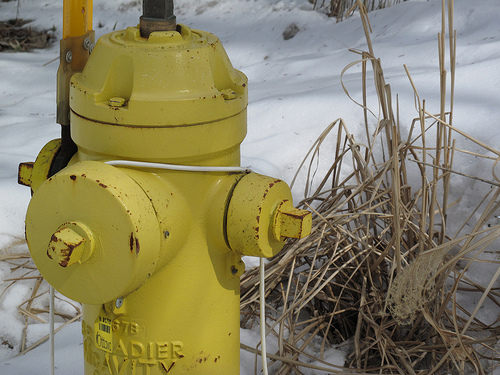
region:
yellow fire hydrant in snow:
[26, 6, 326, 359]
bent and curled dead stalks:
[315, 20, 475, 355]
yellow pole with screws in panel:
[50, 0, 95, 130]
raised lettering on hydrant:
[60, 317, 197, 369]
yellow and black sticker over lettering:
[60, 307, 145, 357]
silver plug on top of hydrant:
[125, 0, 180, 40]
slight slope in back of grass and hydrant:
[21, 5, 486, 140]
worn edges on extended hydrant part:
[11, 177, 163, 302]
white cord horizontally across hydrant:
[70, 141, 265, 187]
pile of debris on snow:
[0, 8, 56, 66]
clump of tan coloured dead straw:
[235, 3, 498, 373]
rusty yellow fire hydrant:
[12, 14, 318, 373]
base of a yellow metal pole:
[51, 0, 105, 138]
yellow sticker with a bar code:
[82, 317, 127, 357]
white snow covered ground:
[2, 0, 499, 373]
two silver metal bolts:
[51, 34, 99, 73]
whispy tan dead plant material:
[382, 236, 452, 325]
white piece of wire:
[95, 150, 275, 185]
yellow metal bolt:
[102, 86, 132, 113]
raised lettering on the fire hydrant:
[76, 316, 188, 373]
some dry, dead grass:
[242, 50, 482, 370]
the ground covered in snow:
[1, 4, 482, 367]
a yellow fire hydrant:
[1, 20, 267, 370]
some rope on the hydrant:
[16, 146, 301, 373]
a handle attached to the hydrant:
[24, 1, 99, 128]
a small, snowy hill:
[258, 0, 497, 160]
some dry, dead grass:
[313, 1, 390, 31]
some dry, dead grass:
[0, 7, 50, 51]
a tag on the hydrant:
[83, 306, 132, 363]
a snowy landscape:
[3, 5, 498, 341]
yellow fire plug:
[72, 18, 272, 373]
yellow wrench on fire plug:
[36, 1, 96, 145]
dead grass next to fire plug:
[270, 37, 455, 334]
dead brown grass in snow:
[280, 47, 490, 365]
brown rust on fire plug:
[36, 68, 245, 372]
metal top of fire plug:
[128, 2, 186, 34]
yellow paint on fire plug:
[47, 147, 187, 355]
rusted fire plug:
[16, 147, 161, 310]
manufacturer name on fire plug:
[88, 295, 210, 374]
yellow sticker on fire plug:
[85, 310, 125, 362]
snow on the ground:
[272, 71, 339, 129]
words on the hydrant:
[90, 305, 170, 371]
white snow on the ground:
[276, 70, 322, 115]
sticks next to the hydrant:
[356, 131, 456, 231]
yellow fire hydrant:
[35, 30, 298, 346]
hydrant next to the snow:
[79, 27, 304, 256]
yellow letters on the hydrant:
[128, 328, 175, 371]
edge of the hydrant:
[281, 187, 319, 254]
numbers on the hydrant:
[110, 309, 145, 336]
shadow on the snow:
[286, 56, 335, 132]